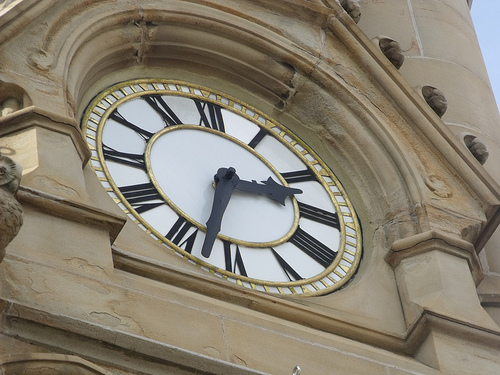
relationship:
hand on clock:
[218, 167, 304, 206] [77, 77, 367, 310]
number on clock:
[291, 231, 341, 272] [77, 77, 367, 310]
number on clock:
[136, 84, 188, 143] [76, 34, 375, 304]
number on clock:
[159, 201, 215, 261] [90, 28, 421, 353]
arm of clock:
[226, 165, 304, 206] [88, 39, 368, 264]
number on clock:
[122, 175, 162, 210] [76, 34, 375, 304]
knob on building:
[464, 134, 486, 166] [354, 77, 484, 280]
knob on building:
[413, 79, 453, 123] [4, 2, 497, 374]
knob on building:
[463, 134, 489, 166] [4, 2, 497, 374]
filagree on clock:
[75, 68, 380, 307] [77, 77, 367, 310]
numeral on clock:
[99, 141, 146, 173] [77, 77, 367, 310]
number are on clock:
[287, 224, 338, 268] [77, 77, 367, 310]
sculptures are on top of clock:
[266, 45, 374, 114] [77, 77, 367, 310]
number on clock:
[290, 222, 344, 274] [77, 77, 367, 310]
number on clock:
[298, 202, 343, 230] [77, 77, 367, 310]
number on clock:
[217, 233, 253, 282] [77, 77, 367, 310]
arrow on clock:
[269, 175, 300, 203] [104, 81, 359, 296]